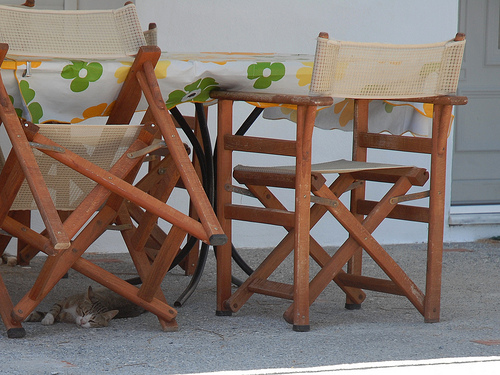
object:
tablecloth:
[0, 52, 454, 138]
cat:
[25, 285, 144, 328]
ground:
[0, 239, 500, 375]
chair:
[0, 0, 225, 340]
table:
[1, 52, 453, 309]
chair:
[208, 31, 467, 332]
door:
[450, 0, 498, 207]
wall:
[0, 0, 460, 254]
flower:
[246, 61, 285, 90]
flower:
[70, 103, 115, 123]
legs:
[214, 221, 444, 333]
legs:
[23, 299, 64, 326]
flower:
[166, 77, 220, 109]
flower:
[60, 60, 103, 93]